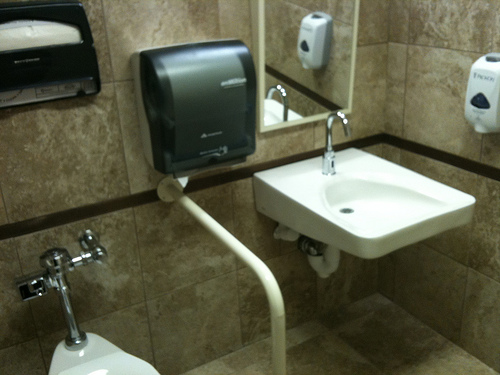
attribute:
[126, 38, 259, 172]
dispenser — paper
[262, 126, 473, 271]
sink — White 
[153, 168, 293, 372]
railing — white 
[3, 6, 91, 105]
container — Black 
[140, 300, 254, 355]
tile — brown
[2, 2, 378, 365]
wall — Brown 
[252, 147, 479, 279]
sink — white 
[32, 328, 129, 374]
toliet — White 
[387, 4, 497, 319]
wall — tiled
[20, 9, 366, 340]
wall — tiled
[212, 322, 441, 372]
floor — tiled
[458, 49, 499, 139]
container — white 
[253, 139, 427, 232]
sink — silver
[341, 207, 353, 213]
drain — silver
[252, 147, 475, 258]
sink — white, square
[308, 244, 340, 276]
pipe — white 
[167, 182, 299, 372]
bar — assistance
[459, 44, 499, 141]
dispenser — white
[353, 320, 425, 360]
floors — tiled, brown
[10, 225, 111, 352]
plumbing — silver, metal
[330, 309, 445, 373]
floor — Brown 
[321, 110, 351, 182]
faucet — Silver 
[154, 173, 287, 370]
rail — beige